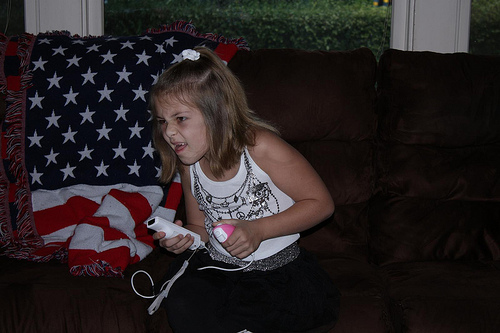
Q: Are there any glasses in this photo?
A: No, there are no glasses.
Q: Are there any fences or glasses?
A: No, there are no glasses or fences.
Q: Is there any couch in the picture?
A: Yes, there is a couch.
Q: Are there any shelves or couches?
A: Yes, there is a couch.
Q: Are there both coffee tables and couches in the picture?
A: No, there is a couch but no coffee tables.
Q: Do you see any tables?
A: No, there are no tables.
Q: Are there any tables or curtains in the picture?
A: No, there are no tables or curtains.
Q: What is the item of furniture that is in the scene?
A: The piece of furniture is a couch.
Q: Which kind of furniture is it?
A: The piece of furniture is a couch.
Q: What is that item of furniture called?
A: This is a couch.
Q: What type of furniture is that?
A: This is a couch.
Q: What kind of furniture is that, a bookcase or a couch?
A: This is a couch.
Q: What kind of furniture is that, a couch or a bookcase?
A: This is a couch.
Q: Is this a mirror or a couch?
A: This is a couch.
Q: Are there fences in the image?
A: No, there are no fences.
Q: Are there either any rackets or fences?
A: No, there are no fences or rackets.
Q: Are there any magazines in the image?
A: No, there are no magazines.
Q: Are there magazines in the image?
A: No, there are no magazines.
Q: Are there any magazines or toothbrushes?
A: No, there are no magazines or toothbrushes.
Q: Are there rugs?
A: No, there are no rugs.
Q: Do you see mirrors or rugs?
A: No, there are no rugs or mirrors.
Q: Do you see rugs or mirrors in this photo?
A: No, there are no rugs or mirrors.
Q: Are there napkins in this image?
A: No, there are no napkins.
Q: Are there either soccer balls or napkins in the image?
A: No, there are no napkins or soccer balls.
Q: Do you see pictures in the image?
A: No, there are no pictures.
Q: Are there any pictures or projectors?
A: No, there are no pictures or projectors.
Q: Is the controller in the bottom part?
A: Yes, the controller is in the bottom of the image.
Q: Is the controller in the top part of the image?
A: No, the controller is in the bottom of the image.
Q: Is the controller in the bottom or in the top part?
A: The controller is in the bottom of the image.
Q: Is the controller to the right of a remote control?
A: Yes, the controller is to the right of a remote control.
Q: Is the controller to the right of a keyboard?
A: No, the controller is to the right of a remote control.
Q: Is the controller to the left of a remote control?
A: No, the controller is to the right of a remote control.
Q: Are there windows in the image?
A: Yes, there is a window.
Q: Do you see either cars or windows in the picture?
A: Yes, there is a window.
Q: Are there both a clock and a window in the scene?
A: No, there is a window but no clocks.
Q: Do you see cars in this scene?
A: No, there are no cars.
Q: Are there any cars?
A: No, there are no cars.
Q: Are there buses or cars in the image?
A: No, there are no cars or buses.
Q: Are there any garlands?
A: No, there are no garlands.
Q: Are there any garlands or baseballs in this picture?
A: No, there are no garlands or baseballs.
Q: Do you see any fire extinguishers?
A: No, there are no fire extinguishers.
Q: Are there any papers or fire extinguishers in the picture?
A: No, there are no fire extinguishers or papers.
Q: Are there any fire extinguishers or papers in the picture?
A: No, there are no fire extinguishers or papers.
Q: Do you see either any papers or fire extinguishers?
A: No, there are no fire extinguishers or papers.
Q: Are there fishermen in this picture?
A: No, there are no fishermen.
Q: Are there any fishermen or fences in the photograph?
A: No, there are no fishermen or fences.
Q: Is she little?
A: Yes, the girl is little.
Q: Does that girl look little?
A: Yes, the girl is little.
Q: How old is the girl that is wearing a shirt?
A: The girl is little.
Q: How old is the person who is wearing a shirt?
A: The girl is little.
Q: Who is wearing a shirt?
A: The girl is wearing a shirt.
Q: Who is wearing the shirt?
A: The girl is wearing a shirt.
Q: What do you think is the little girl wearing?
A: The girl is wearing a shirt.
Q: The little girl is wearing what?
A: The girl is wearing a shirt.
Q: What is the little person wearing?
A: The girl is wearing a shirt.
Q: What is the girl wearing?
A: The girl is wearing a shirt.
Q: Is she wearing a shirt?
A: Yes, the girl is wearing a shirt.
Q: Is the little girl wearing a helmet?
A: No, the girl is wearing a shirt.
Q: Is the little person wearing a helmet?
A: No, the girl is wearing a shirt.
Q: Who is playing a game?
A: The girl is playing a game.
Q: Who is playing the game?
A: The girl is playing a game.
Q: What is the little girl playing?
A: The girl is playing a game.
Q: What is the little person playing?
A: The girl is playing a game.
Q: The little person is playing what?
A: The girl is playing a game.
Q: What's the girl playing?
A: The girl is playing a game.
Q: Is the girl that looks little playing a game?
A: Yes, the girl is playing a game.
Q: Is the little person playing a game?
A: Yes, the girl is playing a game.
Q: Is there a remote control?
A: Yes, there is a remote control.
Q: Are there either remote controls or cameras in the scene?
A: Yes, there is a remote control.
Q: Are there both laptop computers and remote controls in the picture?
A: No, there is a remote control but no laptops.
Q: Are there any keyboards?
A: No, there are no keyboards.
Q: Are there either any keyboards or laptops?
A: No, there are no keyboards or laptops.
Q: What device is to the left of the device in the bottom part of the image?
A: The device is a remote control.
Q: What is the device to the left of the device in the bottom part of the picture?
A: The device is a remote control.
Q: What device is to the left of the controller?
A: The device is a remote control.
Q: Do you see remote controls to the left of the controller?
A: Yes, there is a remote control to the left of the controller.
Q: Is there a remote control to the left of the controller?
A: Yes, there is a remote control to the left of the controller.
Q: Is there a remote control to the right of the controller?
A: No, the remote control is to the left of the controller.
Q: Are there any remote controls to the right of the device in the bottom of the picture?
A: No, the remote control is to the left of the controller.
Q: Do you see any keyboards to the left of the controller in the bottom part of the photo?
A: No, there is a remote control to the left of the controller.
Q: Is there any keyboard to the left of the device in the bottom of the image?
A: No, there is a remote control to the left of the controller.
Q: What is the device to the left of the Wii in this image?
A: The device is a remote control.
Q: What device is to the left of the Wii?
A: The device is a remote control.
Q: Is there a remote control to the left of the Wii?
A: Yes, there is a remote control to the left of the Wii.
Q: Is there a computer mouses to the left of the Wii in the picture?
A: No, there is a remote control to the left of the Wii.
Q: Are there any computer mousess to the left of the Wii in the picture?
A: No, there is a remote control to the left of the Wii.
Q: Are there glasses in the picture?
A: No, there are no glasses.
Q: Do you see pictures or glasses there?
A: No, there are no glasses or pictures.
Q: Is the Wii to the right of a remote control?
A: Yes, the Wii is to the right of a remote control.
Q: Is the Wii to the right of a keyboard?
A: No, the Wii is to the right of a remote control.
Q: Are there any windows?
A: Yes, there is a window.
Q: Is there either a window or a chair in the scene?
A: Yes, there is a window.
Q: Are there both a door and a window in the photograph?
A: No, there is a window but no doors.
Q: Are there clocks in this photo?
A: No, there are no clocks.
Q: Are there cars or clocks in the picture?
A: No, there are no clocks or cars.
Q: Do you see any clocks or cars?
A: No, there are no clocks or cars.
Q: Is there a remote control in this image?
A: Yes, there is a remote control.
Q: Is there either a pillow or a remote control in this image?
A: Yes, there is a remote control.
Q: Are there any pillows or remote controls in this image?
A: Yes, there is a remote control.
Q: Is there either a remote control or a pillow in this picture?
A: Yes, there is a remote control.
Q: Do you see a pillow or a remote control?
A: Yes, there is a remote control.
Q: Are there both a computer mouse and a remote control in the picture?
A: No, there is a remote control but no computer mice.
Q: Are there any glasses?
A: No, there are no glasses.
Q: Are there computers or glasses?
A: No, there are no glasses or computers.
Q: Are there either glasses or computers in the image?
A: No, there are no glasses or computers.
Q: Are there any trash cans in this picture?
A: No, there are no trash cans.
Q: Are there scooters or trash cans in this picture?
A: No, there are no trash cans or scooters.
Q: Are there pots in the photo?
A: No, there are no pots.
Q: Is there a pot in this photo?
A: No, there are no pots.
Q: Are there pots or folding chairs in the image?
A: No, there are no pots or folding chairs.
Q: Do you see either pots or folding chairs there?
A: No, there are no pots or folding chairs.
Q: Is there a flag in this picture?
A: Yes, there is a flag.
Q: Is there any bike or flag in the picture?
A: Yes, there is a flag.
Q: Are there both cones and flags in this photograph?
A: No, there is a flag but no cones.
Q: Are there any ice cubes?
A: No, there are no ice cubes.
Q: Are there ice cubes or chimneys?
A: No, there are no ice cubes or chimneys.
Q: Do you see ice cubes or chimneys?
A: No, there are no ice cubes or chimneys.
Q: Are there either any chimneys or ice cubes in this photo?
A: No, there are no ice cubes or chimneys.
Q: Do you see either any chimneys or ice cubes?
A: No, there are no ice cubes or chimneys.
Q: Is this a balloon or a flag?
A: This is a flag.